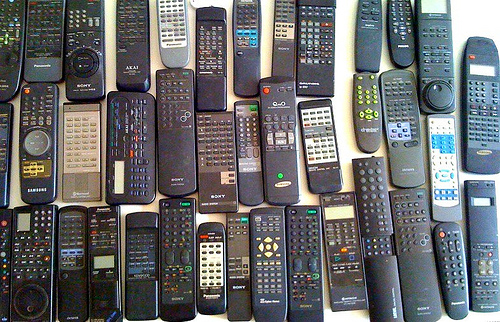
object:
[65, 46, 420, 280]
group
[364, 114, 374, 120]
buttons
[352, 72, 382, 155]
remote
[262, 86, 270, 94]
button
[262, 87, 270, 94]
corner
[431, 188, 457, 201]
areas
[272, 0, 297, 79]
remote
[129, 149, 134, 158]
buttons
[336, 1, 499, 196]
table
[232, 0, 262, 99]
remote control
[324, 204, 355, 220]
screen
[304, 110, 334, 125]
white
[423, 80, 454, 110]
dial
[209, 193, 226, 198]
logo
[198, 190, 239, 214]
bottom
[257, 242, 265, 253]
arrow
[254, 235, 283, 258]
middle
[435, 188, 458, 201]
block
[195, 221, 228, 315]
remote controls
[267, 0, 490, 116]
surface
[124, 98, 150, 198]
keypads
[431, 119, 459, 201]
key pads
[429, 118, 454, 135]
white surface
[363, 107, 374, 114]
keys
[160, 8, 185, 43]
panel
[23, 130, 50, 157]
button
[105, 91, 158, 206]
remote control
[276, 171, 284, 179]
button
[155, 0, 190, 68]
remote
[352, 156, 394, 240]
remote control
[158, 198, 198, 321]
remote control